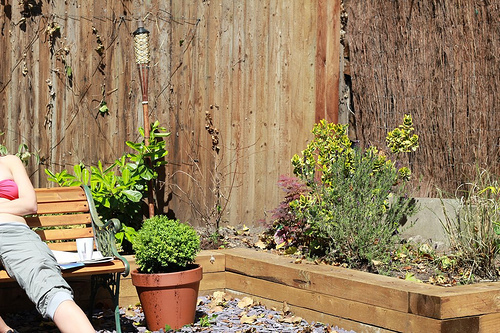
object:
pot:
[126, 266, 209, 333]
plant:
[111, 212, 203, 274]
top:
[0, 175, 23, 203]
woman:
[0, 147, 103, 332]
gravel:
[1, 289, 376, 333]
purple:
[271, 175, 309, 241]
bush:
[261, 113, 424, 265]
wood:
[1, 183, 129, 280]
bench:
[0, 178, 133, 332]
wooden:
[203, 245, 499, 332]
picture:
[1, 1, 500, 333]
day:
[1, 0, 500, 331]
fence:
[1, 0, 342, 229]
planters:
[42, 118, 174, 217]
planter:
[126, 261, 210, 331]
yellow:
[316, 122, 346, 142]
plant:
[295, 147, 424, 271]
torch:
[124, 18, 164, 242]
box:
[124, 246, 498, 333]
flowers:
[277, 113, 425, 184]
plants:
[443, 165, 500, 283]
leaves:
[198, 289, 302, 331]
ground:
[1, 294, 378, 332]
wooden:
[1, 0, 352, 246]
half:
[0, 149, 131, 333]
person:
[0, 147, 93, 333]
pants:
[1, 219, 76, 318]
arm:
[0, 153, 40, 216]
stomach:
[0, 195, 29, 225]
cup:
[73, 236, 97, 263]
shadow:
[1, 281, 126, 332]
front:
[1, 0, 348, 238]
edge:
[0, 259, 128, 283]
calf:
[41, 294, 101, 332]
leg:
[1, 218, 100, 332]